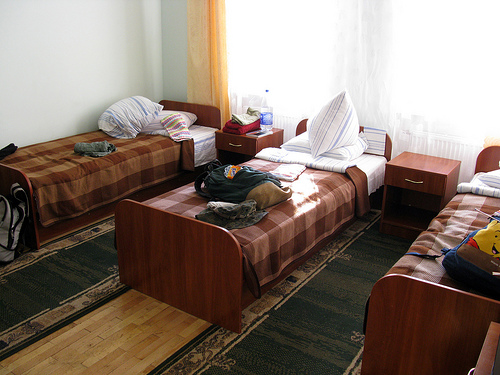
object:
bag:
[192, 161, 295, 211]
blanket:
[3, 128, 195, 228]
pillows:
[308, 88, 361, 158]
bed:
[115, 117, 393, 335]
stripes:
[313, 91, 347, 158]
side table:
[214, 125, 284, 161]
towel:
[221, 120, 261, 135]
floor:
[0, 207, 415, 375]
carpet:
[0, 212, 135, 361]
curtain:
[186, 0, 229, 135]